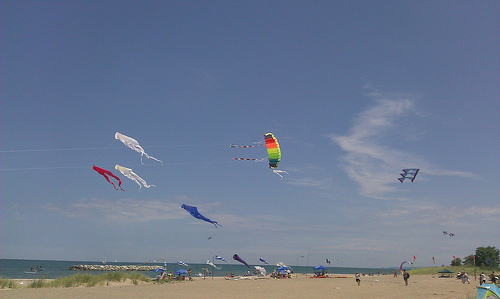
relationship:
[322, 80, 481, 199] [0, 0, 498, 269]
cloud in sky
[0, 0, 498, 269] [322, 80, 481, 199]
sky has cloud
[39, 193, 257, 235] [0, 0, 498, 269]
cloud in sky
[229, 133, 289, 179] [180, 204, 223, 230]
kite flies near kite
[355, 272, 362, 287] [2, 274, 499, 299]
person on beach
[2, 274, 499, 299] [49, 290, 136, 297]
beach has sand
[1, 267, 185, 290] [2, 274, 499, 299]
grass on beach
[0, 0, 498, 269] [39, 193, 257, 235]
sky has cloud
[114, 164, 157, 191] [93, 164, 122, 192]
kite near kite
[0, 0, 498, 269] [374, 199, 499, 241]
sky has cloud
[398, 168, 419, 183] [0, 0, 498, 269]
kite flying in sky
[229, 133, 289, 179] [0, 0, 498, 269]
kite flying in sky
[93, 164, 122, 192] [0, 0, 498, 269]
kite flying in sky